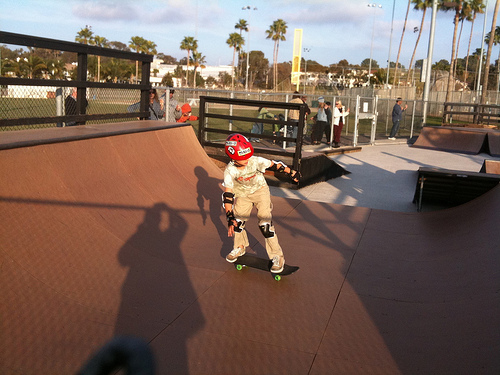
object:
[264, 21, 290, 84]
trees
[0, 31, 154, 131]
fence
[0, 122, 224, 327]
ramp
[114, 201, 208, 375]
shadow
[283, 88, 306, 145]
people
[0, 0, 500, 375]
scene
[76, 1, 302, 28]
clouds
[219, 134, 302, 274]
skater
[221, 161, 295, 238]
safety gear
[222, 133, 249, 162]
helmet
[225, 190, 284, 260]
pants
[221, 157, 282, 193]
shirt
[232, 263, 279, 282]
wheels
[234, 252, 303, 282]
skateboard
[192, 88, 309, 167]
fence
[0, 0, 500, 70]
sky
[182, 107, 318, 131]
grass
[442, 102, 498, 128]
skate ramp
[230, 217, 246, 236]
knees